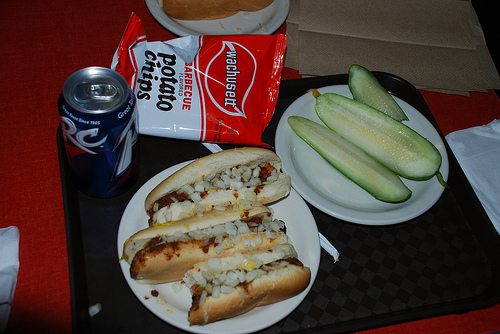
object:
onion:
[89, 303, 102, 317]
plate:
[117, 159, 322, 334]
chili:
[151, 290, 159, 297]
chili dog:
[129, 208, 272, 279]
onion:
[160, 218, 284, 248]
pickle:
[286, 63, 450, 203]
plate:
[274, 85, 449, 226]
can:
[57, 66, 139, 200]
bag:
[111, 12, 287, 150]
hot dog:
[266, 165, 277, 173]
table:
[1, 0, 497, 333]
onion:
[195, 166, 261, 192]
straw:
[201, 142, 341, 265]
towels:
[284, 0, 499, 98]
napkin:
[444, 119, 499, 237]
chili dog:
[188, 257, 304, 312]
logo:
[205, 41, 258, 118]